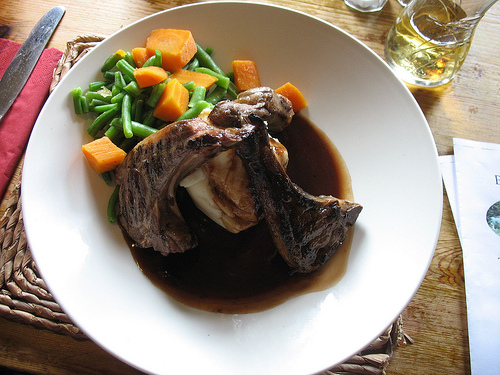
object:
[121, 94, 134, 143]
beans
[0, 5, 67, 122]
knife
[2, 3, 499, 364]
table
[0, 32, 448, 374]
pad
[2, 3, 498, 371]
wooden table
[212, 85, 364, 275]
food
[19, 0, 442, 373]
bowl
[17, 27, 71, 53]
top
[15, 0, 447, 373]
plate